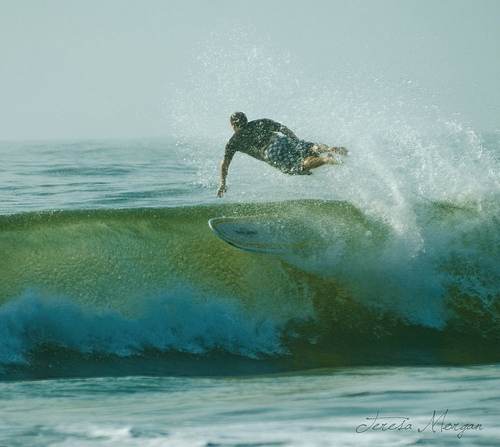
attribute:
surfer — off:
[175, 67, 386, 238]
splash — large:
[354, 119, 454, 273]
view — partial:
[15, 20, 181, 131]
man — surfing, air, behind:
[143, 87, 411, 246]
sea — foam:
[406, 129, 479, 218]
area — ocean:
[39, 153, 174, 208]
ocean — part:
[36, 243, 181, 409]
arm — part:
[204, 151, 247, 209]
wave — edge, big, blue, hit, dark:
[292, 194, 370, 240]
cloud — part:
[167, 36, 198, 75]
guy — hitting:
[195, 77, 387, 244]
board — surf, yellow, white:
[178, 183, 386, 300]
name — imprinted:
[347, 390, 484, 447]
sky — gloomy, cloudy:
[58, 29, 168, 137]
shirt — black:
[238, 125, 284, 157]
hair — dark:
[226, 113, 252, 133]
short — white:
[268, 135, 320, 181]